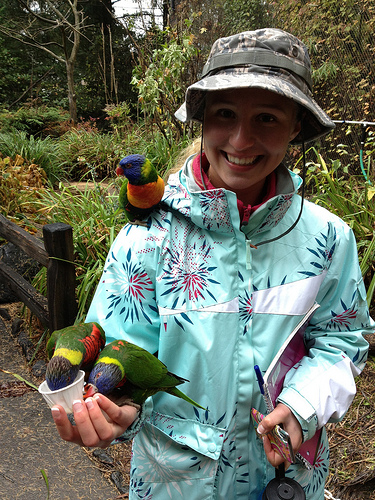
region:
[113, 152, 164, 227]
a small colorful bird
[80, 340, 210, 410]
a small colorful bird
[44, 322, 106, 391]
a small colorful bird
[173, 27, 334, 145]
a grey bucket hat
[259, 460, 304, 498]
a black water bottle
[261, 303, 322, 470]
a pink spiral notebook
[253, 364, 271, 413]
a pen with blue ink cap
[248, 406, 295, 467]
a cell phone with colorful cover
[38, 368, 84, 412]
a white paper cup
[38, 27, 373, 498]
a woman feeding birds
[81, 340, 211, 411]
A small green parrot.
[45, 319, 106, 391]
A parrot eating out of cup.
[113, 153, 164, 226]
A parrot with a blue head.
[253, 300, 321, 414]
A notebook and pen.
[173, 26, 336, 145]
A camouflage color hat.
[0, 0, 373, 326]
Background of trees and bushes.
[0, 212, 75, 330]
A wood rail fence.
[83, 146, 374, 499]
A blue rain coat.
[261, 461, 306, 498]
A black water bottle lid.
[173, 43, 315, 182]
face of the girl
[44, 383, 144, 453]
hand of the girl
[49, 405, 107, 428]
fingers of the girl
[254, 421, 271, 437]
nail of the girl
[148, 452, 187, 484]
design on the shirt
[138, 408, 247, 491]
pocket in the shirt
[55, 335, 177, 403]
a parrot in hand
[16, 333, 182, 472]
a girl holding parrots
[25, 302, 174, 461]
parrots on the hand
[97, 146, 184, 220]
a parrot sitting in top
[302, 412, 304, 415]
part of a jacket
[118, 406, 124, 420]
part of a finger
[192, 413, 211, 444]
part of a jacket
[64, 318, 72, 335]
part of a fence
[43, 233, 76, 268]
edge of a fence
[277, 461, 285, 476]
part of a bottle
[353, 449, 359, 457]
part of a grass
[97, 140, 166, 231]
A bird on her shoulder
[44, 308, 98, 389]
A bird is eating food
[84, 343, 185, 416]
A bird is eating food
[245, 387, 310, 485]
She is holding a cell phone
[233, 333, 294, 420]
She is holding a pen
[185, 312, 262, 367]
She has a blue shirt on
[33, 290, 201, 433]
Two birds are eating food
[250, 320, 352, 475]
She is holding a notebook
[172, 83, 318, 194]
She is smiling well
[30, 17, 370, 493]
A woman is feeding birds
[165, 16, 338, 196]
Hat on the lady's head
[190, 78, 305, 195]
The lady is smiling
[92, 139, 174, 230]
A blue, green and yellow bird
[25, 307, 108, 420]
A bird is eating from a white container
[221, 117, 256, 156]
Nose on lady's face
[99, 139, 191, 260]
A bird sitting on a shoulder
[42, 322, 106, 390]
large feathered green bird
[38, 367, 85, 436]
small round white cup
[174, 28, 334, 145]
large cloth green hat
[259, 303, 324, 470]
large square paper book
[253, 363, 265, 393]
thin black plastic pen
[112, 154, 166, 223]
large blue and orange bird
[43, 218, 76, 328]
large thick brown post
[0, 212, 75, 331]
large wide wooden fence